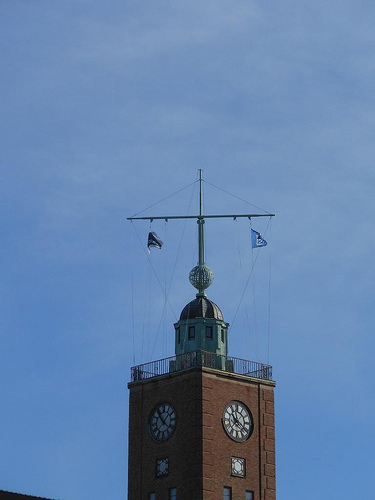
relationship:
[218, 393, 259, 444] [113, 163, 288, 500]
clock on tower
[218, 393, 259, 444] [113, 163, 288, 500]
clock on a tower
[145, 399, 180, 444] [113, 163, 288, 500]
clocks on a tower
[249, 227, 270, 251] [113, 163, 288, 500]
flags on tower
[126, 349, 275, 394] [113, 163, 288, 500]
railing on tower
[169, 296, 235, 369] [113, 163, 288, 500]
dome on tower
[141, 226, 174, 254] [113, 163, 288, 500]
flag on building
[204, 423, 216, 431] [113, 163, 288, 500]
brick on building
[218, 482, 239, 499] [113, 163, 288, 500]
window on tower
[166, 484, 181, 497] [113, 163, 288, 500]
window on tower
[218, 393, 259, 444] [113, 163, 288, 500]
clock on a building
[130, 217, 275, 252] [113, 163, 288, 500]
flags on a building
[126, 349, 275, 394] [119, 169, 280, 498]
area on building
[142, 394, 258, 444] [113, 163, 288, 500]
clocks on a building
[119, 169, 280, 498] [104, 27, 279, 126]
building during day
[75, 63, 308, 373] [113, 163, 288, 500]
sky behind building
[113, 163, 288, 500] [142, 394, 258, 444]
building with clocks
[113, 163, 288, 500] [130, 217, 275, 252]
building with flags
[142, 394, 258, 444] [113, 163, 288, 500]
clocks on tower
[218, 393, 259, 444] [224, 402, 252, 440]
clock has numbers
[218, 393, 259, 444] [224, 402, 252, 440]
clock has hands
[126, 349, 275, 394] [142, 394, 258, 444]
railing above clocks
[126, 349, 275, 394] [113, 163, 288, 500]
railing on building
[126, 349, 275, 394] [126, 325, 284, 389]
fence on top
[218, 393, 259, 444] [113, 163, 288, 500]
clock in a building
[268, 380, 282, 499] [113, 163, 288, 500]
corner of a building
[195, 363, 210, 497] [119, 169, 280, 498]
corner on a building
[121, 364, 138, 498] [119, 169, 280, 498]
corner on a building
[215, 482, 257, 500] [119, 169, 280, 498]
windows on building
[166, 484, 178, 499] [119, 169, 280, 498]
window on building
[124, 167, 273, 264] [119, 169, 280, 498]
mast on a building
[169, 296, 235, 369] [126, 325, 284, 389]
dome on top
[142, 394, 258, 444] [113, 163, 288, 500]
clocks on a tower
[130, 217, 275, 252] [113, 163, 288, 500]
flags on tower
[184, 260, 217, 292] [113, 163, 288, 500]
globe on tower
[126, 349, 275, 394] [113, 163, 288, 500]
fence on tower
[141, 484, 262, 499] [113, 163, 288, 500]
windows on tower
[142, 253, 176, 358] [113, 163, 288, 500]
cables on tower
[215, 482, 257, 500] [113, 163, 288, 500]
windows on tower